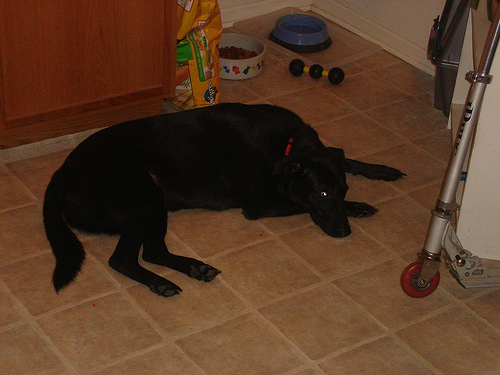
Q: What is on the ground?
A: The dog.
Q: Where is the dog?
A: On the ground.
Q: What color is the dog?
A: Black.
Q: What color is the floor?
A: Tan.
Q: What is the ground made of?
A: Tile.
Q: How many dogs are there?
A: One.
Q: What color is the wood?
A: Brown.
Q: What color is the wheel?
A: Red.